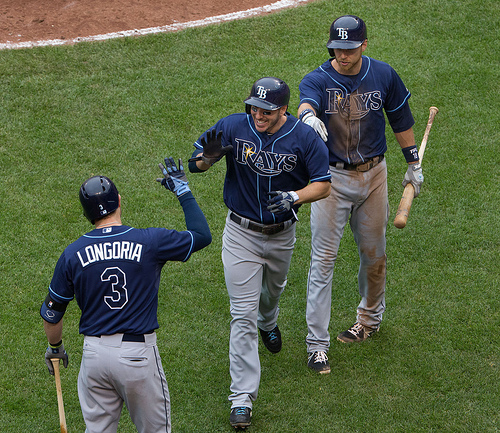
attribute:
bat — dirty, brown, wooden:
[365, 48, 451, 251]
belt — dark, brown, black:
[224, 202, 306, 246]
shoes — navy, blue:
[296, 293, 392, 382]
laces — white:
[298, 326, 409, 386]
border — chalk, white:
[1, 0, 321, 91]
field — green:
[0, 0, 491, 217]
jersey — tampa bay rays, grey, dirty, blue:
[290, 38, 435, 176]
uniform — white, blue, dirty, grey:
[290, 41, 432, 338]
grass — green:
[2, 0, 483, 63]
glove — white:
[293, 104, 352, 149]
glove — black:
[185, 117, 249, 174]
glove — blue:
[134, 135, 203, 201]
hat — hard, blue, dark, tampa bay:
[309, 3, 388, 69]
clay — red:
[2, 2, 240, 29]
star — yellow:
[240, 145, 258, 162]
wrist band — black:
[385, 132, 431, 169]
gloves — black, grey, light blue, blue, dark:
[141, 149, 209, 210]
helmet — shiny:
[319, 8, 379, 50]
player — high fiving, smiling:
[166, 55, 332, 429]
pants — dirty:
[303, 142, 431, 374]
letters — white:
[335, 26, 350, 37]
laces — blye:
[263, 322, 286, 351]